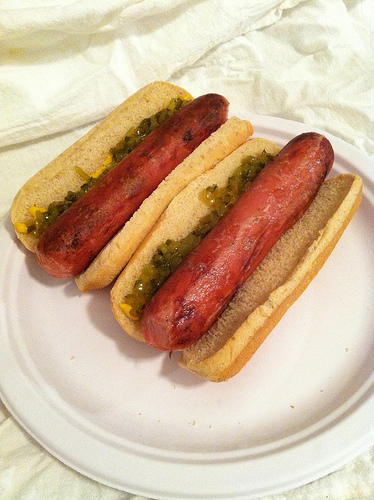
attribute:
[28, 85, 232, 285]
hot dog — wrinkly , brown , cooked 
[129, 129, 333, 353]
hot dog — wheat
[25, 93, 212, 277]
hot dog — grilled 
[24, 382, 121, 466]
mat — white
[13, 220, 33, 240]
mustard — yellow 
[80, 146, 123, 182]
mustard — yellow 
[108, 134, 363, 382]
sandwich — appetising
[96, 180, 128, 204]
sausage — red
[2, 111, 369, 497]
paper plate — white, round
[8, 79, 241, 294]
hotdog — cooked , brown , wrinkly 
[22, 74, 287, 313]
relish — green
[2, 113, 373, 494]
plate — white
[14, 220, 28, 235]
dob — yellow 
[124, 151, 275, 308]
relish — green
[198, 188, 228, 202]
paste — green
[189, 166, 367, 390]
bread — brown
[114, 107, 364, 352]
sausage — red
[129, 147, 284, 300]
relish — green